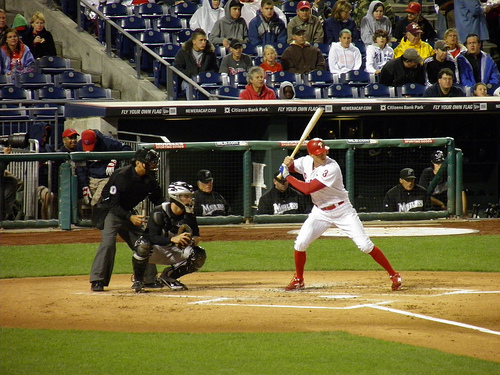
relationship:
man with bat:
[294, 133, 396, 292] [279, 102, 323, 183]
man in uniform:
[294, 133, 396, 292] [292, 159, 370, 249]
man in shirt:
[397, 22, 435, 59] [396, 39, 434, 60]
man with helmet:
[139, 178, 206, 284] [167, 179, 195, 213]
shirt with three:
[294, 154, 351, 204] [322, 166, 331, 179]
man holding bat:
[294, 133, 396, 292] [279, 102, 323, 183]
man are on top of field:
[130, 178, 206, 292] [16, 216, 486, 374]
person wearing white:
[328, 28, 363, 78] [329, 43, 363, 74]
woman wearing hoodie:
[241, 66, 273, 99] [243, 81, 274, 99]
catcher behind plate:
[139, 178, 206, 284] [317, 287, 351, 302]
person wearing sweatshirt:
[370, 32, 393, 70] [365, 41, 395, 73]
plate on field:
[317, 287, 351, 302] [16, 216, 486, 374]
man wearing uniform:
[294, 133, 396, 292] [292, 159, 370, 249]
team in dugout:
[196, 162, 449, 211] [83, 97, 500, 218]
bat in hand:
[279, 102, 323, 183] [277, 155, 293, 174]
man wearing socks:
[294, 133, 396, 292] [284, 246, 400, 277]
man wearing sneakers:
[294, 133, 396, 292] [285, 266, 402, 293]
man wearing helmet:
[99, 141, 162, 286] [130, 147, 162, 180]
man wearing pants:
[99, 141, 162, 286] [93, 204, 150, 287]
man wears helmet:
[139, 178, 206, 284] [167, 179, 195, 213]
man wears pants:
[294, 133, 396, 292] [291, 199, 375, 257]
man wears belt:
[294, 133, 396, 292] [310, 200, 349, 210]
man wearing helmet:
[294, 133, 396, 292] [305, 137, 330, 155]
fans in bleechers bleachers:
[205, 11, 491, 91] [12, 13, 483, 95]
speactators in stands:
[205, 11, 491, 91] [12, 13, 483, 95]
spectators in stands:
[205, 11, 491, 91] [12, 13, 483, 95]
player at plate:
[294, 133, 396, 292] [317, 287, 351, 302]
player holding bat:
[294, 133, 396, 292] [279, 102, 323, 183]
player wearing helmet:
[294, 133, 396, 292] [305, 137, 330, 155]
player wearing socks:
[294, 133, 396, 292] [284, 246, 400, 277]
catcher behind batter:
[139, 178, 206, 284] [294, 133, 396, 292]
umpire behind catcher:
[99, 141, 162, 286] [139, 178, 206, 284]